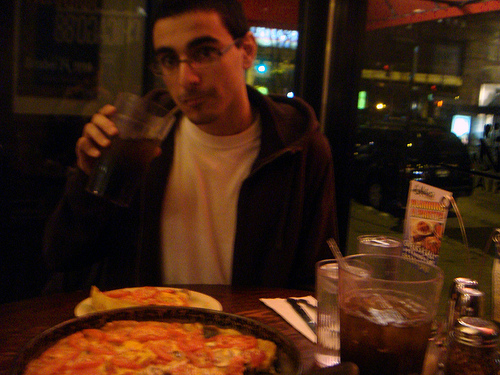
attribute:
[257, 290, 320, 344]
napkin — white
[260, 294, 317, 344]
napkin — white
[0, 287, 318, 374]
table — brown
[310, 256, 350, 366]
glass — full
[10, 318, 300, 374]
pizza — deep dish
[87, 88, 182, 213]
cup — clear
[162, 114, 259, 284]
shirt — white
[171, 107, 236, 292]
shirt — t-shirt, white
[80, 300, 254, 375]
tomatoes — sliced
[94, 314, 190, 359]
tomatoes — sliced